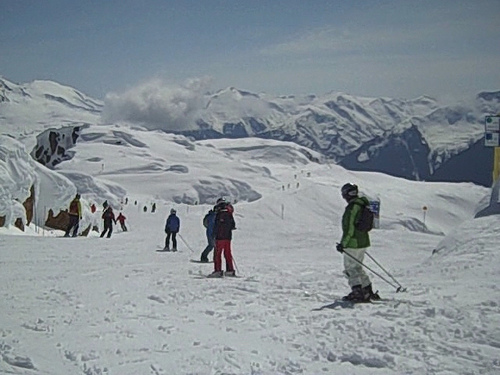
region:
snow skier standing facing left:
[325, 179, 405, 307]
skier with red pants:
[205, 193, 244, 281]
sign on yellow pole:
[478, 112, 498, 205]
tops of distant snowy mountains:
[2, 65, 497, 139]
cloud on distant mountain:
[100, 71, 211, 134]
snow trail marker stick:
[276, 199, 287, 225]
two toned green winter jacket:
[337, 197, 371, 257]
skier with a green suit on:
[319, 150, 403, 310]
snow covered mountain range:
[203, 80, 498, 130]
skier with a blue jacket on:
[150, 207, 192, 259]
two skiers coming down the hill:
[102, 194, 132, 239]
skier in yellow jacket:
[62, 189, 87, 234]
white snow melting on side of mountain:
[38, 120, 103, 162]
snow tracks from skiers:
[127, 280, 269, 363]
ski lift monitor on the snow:
[413, 195, 435, 230]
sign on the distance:
[474, 97, 499, 207]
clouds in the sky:
[254, 15, 481, 81]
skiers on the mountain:
[59, 182, 399, 306]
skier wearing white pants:
[320, 177, 401, 306]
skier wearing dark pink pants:
[207, 198, 239, 280]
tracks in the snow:
[117, 239, 499, 373]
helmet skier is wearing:
[340, 182, 357, 195]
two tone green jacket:
[335, 199, 369, 247]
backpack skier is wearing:
[354, 198, 371, 230]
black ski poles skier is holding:
[335, 241, 403, 291]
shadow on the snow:
[306, 297, 355, 315]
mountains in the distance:
[4, 75, 499, 177]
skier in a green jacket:
[335, 182, 407, 299]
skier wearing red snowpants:
[210, 197, 238, 279]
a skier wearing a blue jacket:
[161, 208, 181, 252]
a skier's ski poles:
[335, 243, 406, 294]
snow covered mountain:
[0, 79, 498, 371]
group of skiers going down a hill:
[67, 180, 411, 305]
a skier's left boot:
[340, 285, 364, 302]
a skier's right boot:
[224, 268, 236, 275]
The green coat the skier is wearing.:
[340, 194, 368, 251]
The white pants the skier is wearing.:
[343, 241, 365, 292]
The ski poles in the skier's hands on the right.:
[337, 247, 399, 302]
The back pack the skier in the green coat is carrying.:
[357, 197, 372, 235]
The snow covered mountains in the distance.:
[0, 74, 495, 179]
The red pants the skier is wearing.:
[217, 240, 231, 267]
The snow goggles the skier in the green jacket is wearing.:
[343, 191, 360, 195]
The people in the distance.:
[106, 178, 176, 215]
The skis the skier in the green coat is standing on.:
[322, 280, 422, 312]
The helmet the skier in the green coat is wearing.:
[342, 181, 357, 193]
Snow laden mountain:
[19, 47, 459, 351]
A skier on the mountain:
[328, 179, 414, 313]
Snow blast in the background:
[98, 75, 245, 147]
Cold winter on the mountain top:
[9, 10, 492, 353]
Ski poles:
[335, 231, 416, 295]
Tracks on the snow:
[176, 267, 458, 369]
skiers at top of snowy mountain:
[18, 58, 464, 333]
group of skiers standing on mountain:
[148, 161, 257, 290]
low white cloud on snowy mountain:
[104, 58, 269, 161]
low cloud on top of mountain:
[91, 54, 258, 148]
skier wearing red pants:
[206, 197, 261, 295]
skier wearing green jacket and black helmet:
[321, 161, 424, 313]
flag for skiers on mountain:
[408, 188, 448, 247]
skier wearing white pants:
[335, 183, 377, 303]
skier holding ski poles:
[335, 243, 408, 296]